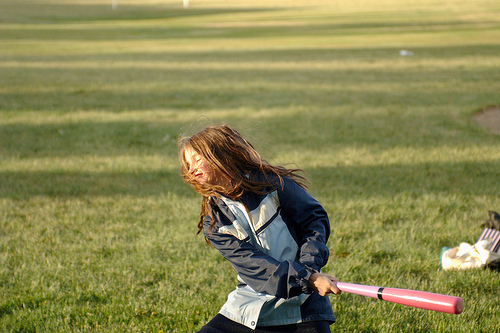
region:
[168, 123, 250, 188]
head of a person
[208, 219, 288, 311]
arm of a person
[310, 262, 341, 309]
hand of a person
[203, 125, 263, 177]
hair of a person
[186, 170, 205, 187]
mouth of a person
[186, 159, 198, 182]
nose of a person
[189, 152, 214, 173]
eye of a person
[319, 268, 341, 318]
fingers of a person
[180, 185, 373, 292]
body of a person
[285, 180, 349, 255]
arm of a person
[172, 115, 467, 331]
A young girl playing baseball in a park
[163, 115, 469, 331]
A young girl playing baseball in a park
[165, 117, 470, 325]
A young girl playing baseball in a park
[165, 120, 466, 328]
A young girl playing baseball in a park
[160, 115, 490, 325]
A young girl playing baseball in a park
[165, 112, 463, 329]
A young girl playing baseball in a park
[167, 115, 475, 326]
A young girl playing baseball in a park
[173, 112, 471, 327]
A young girl playing baseball in a park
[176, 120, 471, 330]
A young girl playing baseball in a park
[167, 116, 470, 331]
A young girl playing baseball in a park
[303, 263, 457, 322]
Girl holding a bat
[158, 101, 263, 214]
girl with blond hair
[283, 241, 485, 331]
girl holding a pink bat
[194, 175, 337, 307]
girl wearing a blue jacket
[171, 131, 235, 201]
girl with hair in her face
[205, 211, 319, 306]
girl wearing a blue and grey jacket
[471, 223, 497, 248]
striped bag on the ground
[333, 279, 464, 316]
A base ball bat.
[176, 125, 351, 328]
A young girl has fun in the park.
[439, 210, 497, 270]
The little girl's belongings.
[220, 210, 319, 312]
The girl's coat.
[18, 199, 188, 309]
The long green grass of the park.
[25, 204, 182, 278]
The sun shines on the grass.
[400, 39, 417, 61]
Trash laying on the park.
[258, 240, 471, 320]
The girl swings the bat.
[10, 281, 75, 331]
Small patch of green grass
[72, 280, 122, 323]
Small patch of green grass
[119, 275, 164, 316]
Small patch of green grass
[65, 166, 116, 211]
Small patch of green grass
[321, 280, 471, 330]
Pink and black baseball bat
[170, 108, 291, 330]
Small child in the grass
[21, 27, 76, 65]
Small patch of green grass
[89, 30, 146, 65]
Small patch of green grass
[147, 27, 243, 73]
Small patch of green grass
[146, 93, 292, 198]
head of the girl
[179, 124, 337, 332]
small girl swinging a bat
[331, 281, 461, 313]
small pink wooden bat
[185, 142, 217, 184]
small girls white face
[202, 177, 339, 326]
dark and white jacket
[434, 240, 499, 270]
white bundle of cloths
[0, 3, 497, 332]
large grass covered field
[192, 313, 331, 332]
black cloth long pants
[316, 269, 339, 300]
small white slender hand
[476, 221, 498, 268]
black striped bag in grass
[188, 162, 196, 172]
small white girls nose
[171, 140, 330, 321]
girl wearing a blue and gray jacket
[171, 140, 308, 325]
girl whit long hair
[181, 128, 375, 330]
girl holding a pink bat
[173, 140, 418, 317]
a girl playing in the grass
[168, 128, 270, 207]
girl with brown hair